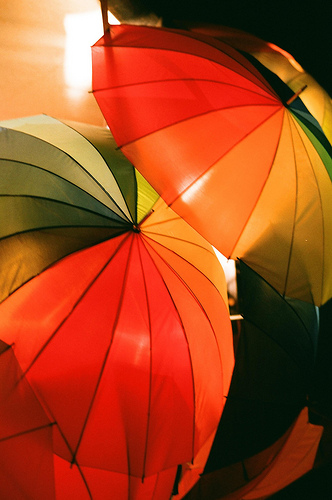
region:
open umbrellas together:
[14, 5, 328, 355]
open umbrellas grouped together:
[17, 68, 325, 421]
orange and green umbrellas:
[27, 61, 281, 381]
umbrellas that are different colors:
[32, 68, 303, 383]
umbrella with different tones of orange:
[20, 100, 326, 401]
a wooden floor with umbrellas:
[10, 5, 123, 127]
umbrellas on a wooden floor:
[19, 9, 229, 206]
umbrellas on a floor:
[15, 19, 316, 252]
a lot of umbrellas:
[69, 36, 322, 331]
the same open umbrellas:
[10, 39, 319, 353]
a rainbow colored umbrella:
[91, 10, 330, 306]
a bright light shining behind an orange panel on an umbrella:
[173, 163, 210, 201]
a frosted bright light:
[65, 8, 118, 108]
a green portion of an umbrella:
[218, 226, 317, 471]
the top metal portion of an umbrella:
[284, 85, 307, 103]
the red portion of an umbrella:
[0, 233, 192, 454]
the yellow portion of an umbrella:
[228, 107, 329, 304]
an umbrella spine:
[133, 227, 201, 471]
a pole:
[98, 2, 138, 137]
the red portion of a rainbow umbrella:
[91, 23, 284, 143]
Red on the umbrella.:
[115, 57, 220, 109]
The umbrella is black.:
[245, 293, 304, 446]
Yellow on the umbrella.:
[267, 194, 330, 291]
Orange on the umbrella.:
[203, 141, 263, 229]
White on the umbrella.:
[26, 115, 116, 208]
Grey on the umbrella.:
[13, 137, 71, 206]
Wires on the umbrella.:
[68, 245, 123, 402]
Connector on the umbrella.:
[119, 210, 160, 256]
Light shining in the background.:
[59, 11, 121, 96]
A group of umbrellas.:
[0, 1, 328, 495]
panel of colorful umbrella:
[128, 255, 150, 478]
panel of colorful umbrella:
[24, 320, 124, 448]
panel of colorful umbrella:
[174, 299, 227, 438]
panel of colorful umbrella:
[248, 126, 280, 293]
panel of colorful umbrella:
[194, 161, 277, 226]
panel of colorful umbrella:
[126, 154, 234, 181]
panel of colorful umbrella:
[87, 112, 235, 137]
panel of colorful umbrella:
[94, 42, 214, 84]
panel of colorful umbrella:
[106, 22, 198, 53]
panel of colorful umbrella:
[0, 280, 40, 365]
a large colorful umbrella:
[100, 36, 329, 271]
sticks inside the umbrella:
[83, 267, 158, 481]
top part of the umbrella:
[133, 204, 159, 227]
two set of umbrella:
[24, 36, 324, 482]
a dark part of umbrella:
[216, 285, 309, 444]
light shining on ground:
[59, 10, 134, 97]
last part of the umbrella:
[84, 19, 164, 204]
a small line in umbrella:
[97, 9, 124, 108]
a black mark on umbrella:
[162, 466, 184, 498]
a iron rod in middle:
[139, 206, 156, 228]